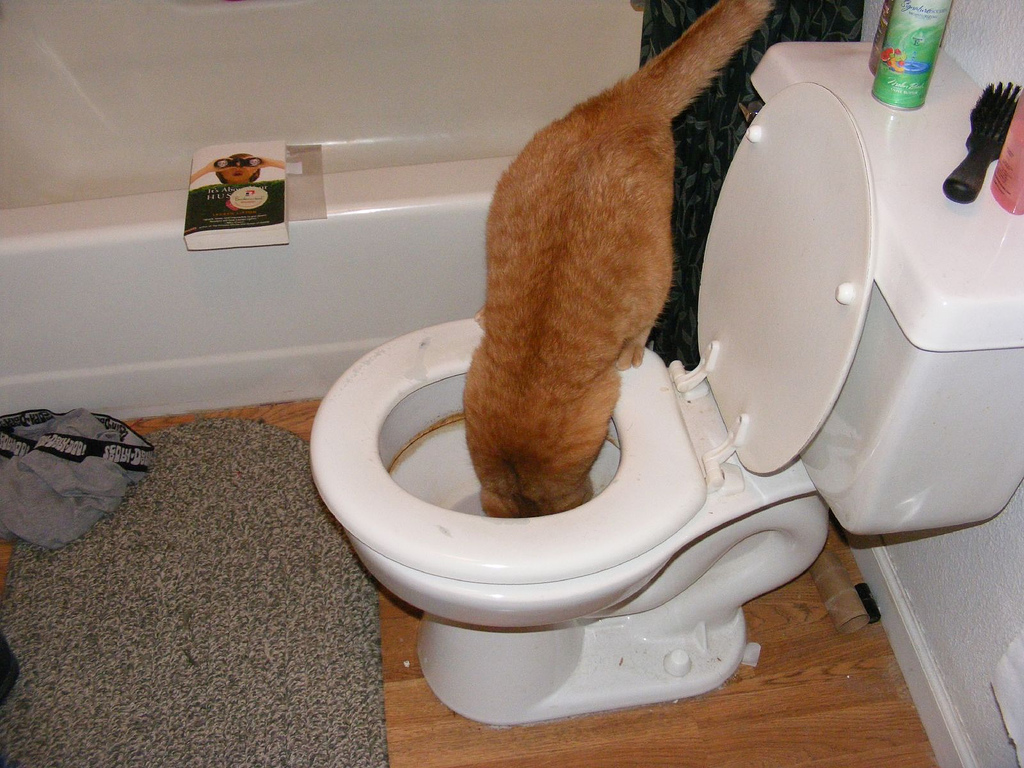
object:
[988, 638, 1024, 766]
paper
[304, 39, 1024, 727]
toilet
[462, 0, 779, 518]
cat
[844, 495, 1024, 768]
wall